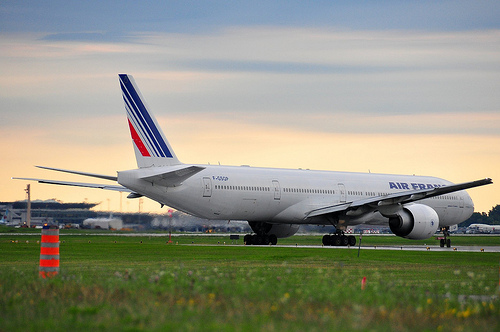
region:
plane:
[41, 62, 483, 257]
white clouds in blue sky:
[425, 68, 445, 93]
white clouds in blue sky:
[215, 48, 242, 73]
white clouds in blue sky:
[184, 5, 226, 62]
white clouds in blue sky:
[77, 22, 151, 62]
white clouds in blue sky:
[22, 33, 60, 77]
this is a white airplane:
[37, 58, 498, 266]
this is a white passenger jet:
[9, 51, 496, 273]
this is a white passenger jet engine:
[13, 51, 495, 265]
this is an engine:
[377, 195, 460, 245]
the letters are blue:
[377, 172, 443, 194]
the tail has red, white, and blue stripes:
[99, 60, 194, 189]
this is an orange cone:
[22, 200, 87, 304]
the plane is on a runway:
[23, 43, 498, 256]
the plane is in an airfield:
[14, 48, 491, 282]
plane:
[20, 72, 497, 270]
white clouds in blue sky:
[315, 86, 370, 108]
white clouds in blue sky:
[380, 88, 458, 115]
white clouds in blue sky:
[414, 35, 486, 96]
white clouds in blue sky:
[240, 43, 327, 115]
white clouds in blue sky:
[22, 81, 64, 109]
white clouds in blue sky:
[214, 35, 311, 113]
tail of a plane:
[62, 69, 193, 193]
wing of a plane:
[92, 72, 183, 146]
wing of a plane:
[119, 166, 209, 214]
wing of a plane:
[397, 169, 478, 216]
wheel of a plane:
[247, 226, 307, 243]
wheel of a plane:
[310, 221, 371, 255]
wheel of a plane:
[436, 222, 474, 244]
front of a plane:
[420, 158, 494, 240]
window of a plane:
[272, 168, 317, 200]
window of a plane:
[202, 175, 272, 200]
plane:
[45, 58, 475, 233]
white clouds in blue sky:
[391, 42, 468, 86]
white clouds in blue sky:
[294, 106, 329, 136]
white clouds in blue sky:
[378, 9, 462, 74]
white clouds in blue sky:
[400, 23, 455, 98]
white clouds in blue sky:
[180, 55, 254, 97]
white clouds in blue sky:
[281, 32, 359, 119]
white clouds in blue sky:
[195, 78, 229, 126]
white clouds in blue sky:
[235, 63, 303, 93]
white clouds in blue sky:
[197, 63, 254, 125]